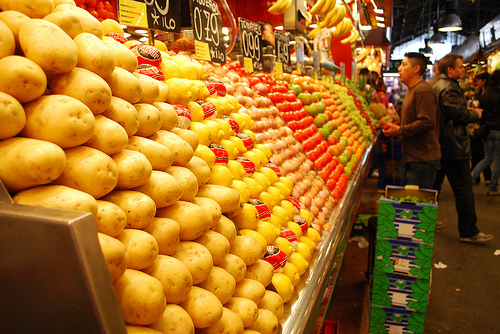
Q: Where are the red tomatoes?
A: Beside the green fruit.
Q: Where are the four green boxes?
A: Near the fruit stand.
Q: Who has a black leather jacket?
A: The man.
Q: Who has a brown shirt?
A: The man.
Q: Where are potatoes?
A: Beside the lemons.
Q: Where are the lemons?
A: In the fruit stand.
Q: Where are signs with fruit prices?
A: Above the fruit.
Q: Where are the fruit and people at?
A: The market.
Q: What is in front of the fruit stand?
A: Green cardboard boxes.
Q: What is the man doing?
A: Choosing fruits.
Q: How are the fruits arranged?
A: In a stack.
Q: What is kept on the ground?
A: Empty boxes.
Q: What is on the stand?
A: Fruits and vegetables.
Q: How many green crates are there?
A: Four.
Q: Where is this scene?
A: A grocery store.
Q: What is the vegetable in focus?
A: Potatoes.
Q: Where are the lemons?
A: Next to the potatoes.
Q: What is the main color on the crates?
A: Green.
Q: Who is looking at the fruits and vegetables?
A: A man.